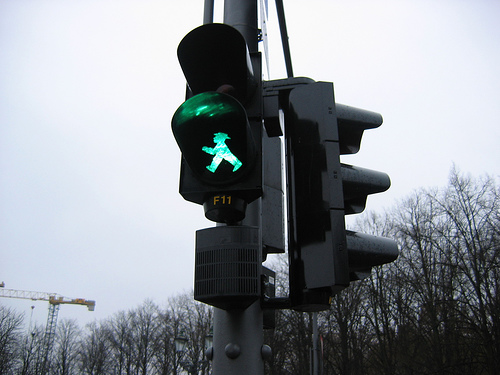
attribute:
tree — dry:
[423, 169, 498, 366]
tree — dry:
[89, 320, 227, 368]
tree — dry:
[2, 310, 31, 373]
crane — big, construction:
[3, 264, 107, 368]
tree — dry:
[454, 171, 494, 338]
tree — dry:
[401, 200, 446, 320]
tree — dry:
[363, 220, 395, 338]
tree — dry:
[168, 304, 183, 373]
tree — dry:
[86, 332, 106, 367]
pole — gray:
[214, 307, 272, 372]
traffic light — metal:
[170, 22, 397, 312]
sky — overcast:
[1, 0, 488, 281]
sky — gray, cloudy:
[0, 0, 499, 372]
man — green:
[199, 122, 249, 184]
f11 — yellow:
[209, 192, 239, 208]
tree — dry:
[387, 153, 497, 367]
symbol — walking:
[197, 127, 243, 175]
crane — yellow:
[0, 289, 98, 312]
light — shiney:
[169, 17, 278, 317]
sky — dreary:
[91, 28, 463, 205]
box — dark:
[267, 76, 399, 309]